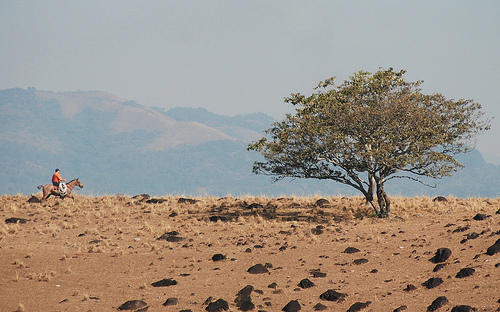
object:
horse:
[35, 175, 84, 201]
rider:
[51, 167, 66, 192]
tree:
[244, 67, 495, 219]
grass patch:
[65, 264, 74, 274]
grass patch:
[83, 294, 89, 302]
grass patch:
[16, 303, 25, 312]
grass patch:
[13, 258, 21, 265]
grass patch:
[38, 270, 50, 282]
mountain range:
[0, 87, 499, 199]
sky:
[0, 0, 500, 166]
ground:
[2, 191, 499, 312]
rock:
[281, 298, 301, 312]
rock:
[297, 278, 316, 289]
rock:
[319, 289, 345, 301]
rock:
[347, 301, 372, 312]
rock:
[313, 303, 328, 312]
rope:
[58, 182, 68, 195]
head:
[52, 167, 60, 174]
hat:
[52, 167, 60, 174]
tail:
[34, 183, 44, 189]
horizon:
[0, 180, 500, 197]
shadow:
[188, 203, 378, 225]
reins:
[64, 181, 82, 190]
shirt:
[50, 173, 61, 182]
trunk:
[357, 186, 380, 215]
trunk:
[374, 180, 389, 219]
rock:
[387, 292, 392, 296]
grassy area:
[0, 192, 499, 284]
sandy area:
[0, 213, 500, 311]